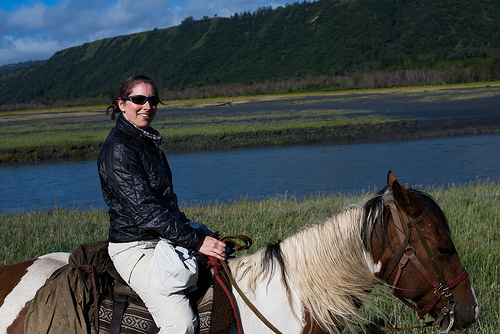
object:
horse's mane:
[232, 51, 254, 193]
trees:
[357, 38, 370, 56]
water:
[1, 134, 500, 211]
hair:
[322, 183, 453, 278]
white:
[282, 232, 358, 291]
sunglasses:
[122, 93, 163, 107]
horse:
[0, 167, 480, 333]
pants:
[108, 239, 200, 333]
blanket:
[20, 239, 159, 331]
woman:
[92, 72, 234, 333]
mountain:
[2, 0, 500, 111]